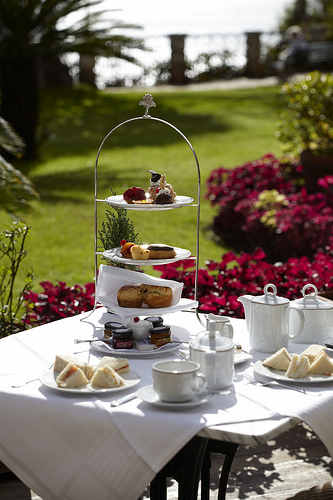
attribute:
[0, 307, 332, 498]
tablecloth — white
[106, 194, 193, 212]
plate — white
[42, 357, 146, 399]
platter — serving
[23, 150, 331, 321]
flowers — red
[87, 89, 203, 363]
pastry display — tiered, metal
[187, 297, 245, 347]
creamer — white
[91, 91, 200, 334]
stand — multiple levels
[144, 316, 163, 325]
jar — one, small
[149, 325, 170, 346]
jar — one, small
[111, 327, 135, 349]
jar — one, small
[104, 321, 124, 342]
jar — one, small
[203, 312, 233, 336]
server — small, white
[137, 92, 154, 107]
piece — decorative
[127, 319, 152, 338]
container — small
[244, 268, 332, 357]
pot — white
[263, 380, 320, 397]
fork — silver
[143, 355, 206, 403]
cup — white, coffee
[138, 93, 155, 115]
decorative piece — silver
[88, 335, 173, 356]
plate — one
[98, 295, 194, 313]
plate — one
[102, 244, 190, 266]
plate — one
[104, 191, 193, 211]
plate — one